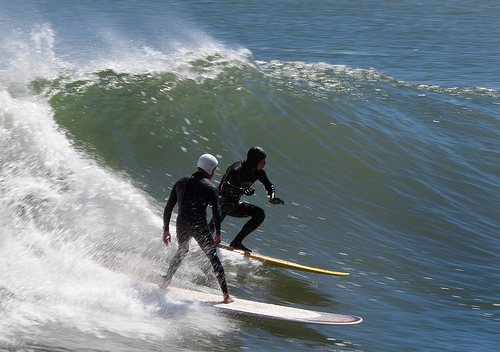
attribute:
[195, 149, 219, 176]
cap — white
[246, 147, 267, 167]
cap — black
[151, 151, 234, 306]
man — wet, surfing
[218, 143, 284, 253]
man — surfing, wearing black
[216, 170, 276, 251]
wetsuit — black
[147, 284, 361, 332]
surfboard — white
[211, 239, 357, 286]
surfboard — yellow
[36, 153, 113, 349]
wave — breaking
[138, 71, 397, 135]
water — big, beautiful